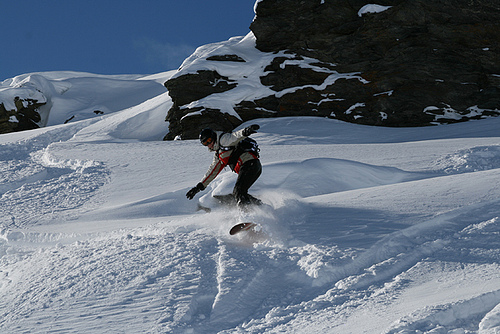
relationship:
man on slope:
[183, 124, 263, 219] [0, 32, 499, 330]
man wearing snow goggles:
[183, 124, 263, 219] [195, 134, 213, 144]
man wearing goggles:
[183, 124, 263, 219] [174, 100, 290, 224]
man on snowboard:
[183, 122, 268, 220] [226, 220, 259, 236]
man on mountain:
[183, 122, 268, 220] [1, 1, 498, 332]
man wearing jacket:
[183, 124, 263, 219] [200, 128, 261, 188]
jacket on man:
[200, 128, 261, 188] [183, 122, 268, 220]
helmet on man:
[196, 129, 217, 143] [181, 116, 271, 220]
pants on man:
[235, 165, 265, 213] [183, 122, 268, 220]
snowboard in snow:
[218, 220, 264, 236] [1, 119, 481, 329]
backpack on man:
[235, 136, 262, 156] [181, 116, 271, 220]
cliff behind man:
[150, 0, 482, 140] [183, 124, 263, 219]